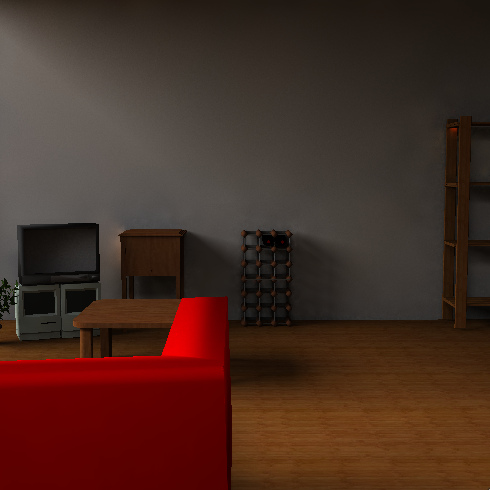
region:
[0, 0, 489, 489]
A living room with white walls.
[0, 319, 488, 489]
Brown tile on the floor.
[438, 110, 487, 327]
Edge of a brown wooden shelved stand.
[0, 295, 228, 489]
Back and side arm of a red sofa.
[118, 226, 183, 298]
A brown wooden stand.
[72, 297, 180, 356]
A brown wooden coffee table.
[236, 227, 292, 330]
A wine rack holding two bottles of wine.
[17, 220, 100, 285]
A black television.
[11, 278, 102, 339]
A stand made out of two old monitors.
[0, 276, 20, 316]
Portion of a plant next to the television.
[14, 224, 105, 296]
Television on the stand.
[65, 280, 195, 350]
The table is wooden.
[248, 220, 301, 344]
Wine bottle rack against the wall.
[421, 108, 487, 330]
A wooden shelf against the wall.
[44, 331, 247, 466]
The sofa is orange.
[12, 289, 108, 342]
The tv stand is white.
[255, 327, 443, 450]
The flooring is hardwood floors.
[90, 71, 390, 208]
The wall is white.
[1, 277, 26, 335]
A green plant by the television.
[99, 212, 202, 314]
A table by the wine rack.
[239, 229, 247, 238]
wooden ball on shelf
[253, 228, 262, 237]
wooden ball on shelf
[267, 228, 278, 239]
wooden ball on shelf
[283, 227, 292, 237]
wooden ball on shelf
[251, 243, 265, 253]
wooden ball on shelf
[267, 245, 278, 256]
wooden ball on shelf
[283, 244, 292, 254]
wooden ball on shelf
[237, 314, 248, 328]
wooden ball on shelf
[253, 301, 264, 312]
wooden ball on shelf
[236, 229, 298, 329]
SYMMETRICAL WINE RACK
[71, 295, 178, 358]
COFFEE TABLE ON THE GROUND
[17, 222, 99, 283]
TELEVISION IN THE ROOM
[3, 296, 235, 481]
ORANGE CORNER COUTCH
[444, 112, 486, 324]
FOUR LEVEL WOODEN SHELVING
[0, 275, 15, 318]
INDOOR PLANTS IN THE ROOM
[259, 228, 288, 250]
TWO BOTTLES OF WINE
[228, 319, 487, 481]
HARD WOOD FLOORING IN THE ROOM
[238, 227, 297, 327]
RECTANGULAR WINE RACK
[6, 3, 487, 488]
a scene in a living room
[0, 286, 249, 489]
a red sofa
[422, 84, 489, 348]
a brown wooden shelf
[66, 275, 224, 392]
a wooden coffee table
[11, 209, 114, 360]
a black tv on a couple of computer monitors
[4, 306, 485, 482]
a hardwood floor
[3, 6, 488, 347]
a gray wall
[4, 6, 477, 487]
a place in a house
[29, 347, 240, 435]
red couch on the floor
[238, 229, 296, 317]
wine wooden shelf in the wall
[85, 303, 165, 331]
little wooden table on the room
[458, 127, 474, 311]
wooden shelf in a corner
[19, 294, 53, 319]
off black sreem in the white compuer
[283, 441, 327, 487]
cgi of a wooden parquet floor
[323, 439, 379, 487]
cgi of a wooden parquet floor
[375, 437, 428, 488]
cgi of a wooden parquet floor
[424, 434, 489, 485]
cgi of a wooden parquet floor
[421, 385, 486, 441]
cgi of a wooden parquet floor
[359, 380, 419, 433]
cgi of a wooden parquet floor